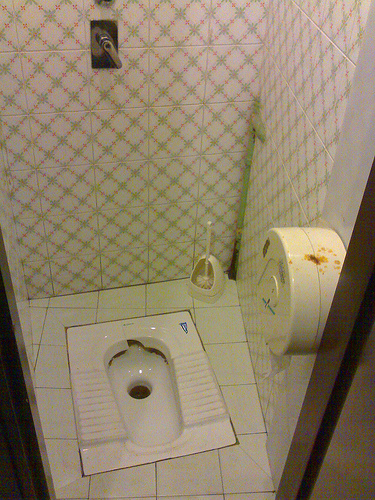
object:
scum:
[288, 246, 341, 275]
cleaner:
[188, 221, 225, 304]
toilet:
[65, 310, 237, 479]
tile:
[0, 0, 375, 443]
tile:
[27, 272, 274, 500]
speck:
[304, 253, 329, 265]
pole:
[228, 96, 266, 280]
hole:
[262, 236, 270, 257]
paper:
[262, 348, 292, 381]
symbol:
[179, 321, 189, 334]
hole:
[129, 385, 150, 399]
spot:
[149, 368, 152, 371]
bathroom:
[0, 0, 375, 500]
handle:
[102, 40, 122, 69]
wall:
[0, 0, 271, 302]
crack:
[237, 442, 274, 480]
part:
[0, 231, 53, 500]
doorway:
[0, 0, 375, 500]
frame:
[255, 227, 348, 357]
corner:
[187, 269, 238, 315]